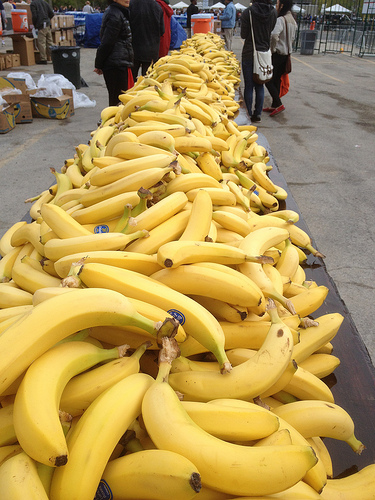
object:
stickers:
[94, 224, 110, 234]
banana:
[77, 263, 233, 373]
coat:
[94, 1, 138, 75]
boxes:
[49, 15, 80, 32]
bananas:
[157, 236, 265, 271]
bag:
[248, 10, 275, 80]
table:
[0, 37, 375, 499]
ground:
[1, 34, 373, 314]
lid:
[10, 8, 26, 12]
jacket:
[92, 2, 135, 74]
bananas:
[93, 446, 203, 500]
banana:
[36, 201, 95, 242]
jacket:
[238, 3, 277, 65]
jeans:
[240, 33, 264, 124]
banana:
[137, 129, 177, 154]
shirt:
[270, 12, 299, 58]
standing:
[236, 1, 273, 124]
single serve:
[74, 261, 236, 374]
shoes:
[268, 103, 285, 116]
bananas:
[290, 312, 344, 366]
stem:
[265, 300, 282, 323]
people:
[94, 0, 134, 111]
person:
[240, 0, 274, 124]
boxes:
[29, 91, 72, 120]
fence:
[297, 0, 374, 63]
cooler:
[188, 15, 213, 35]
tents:
[170, 2, 246, 14]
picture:
[0, 0, 375, 499]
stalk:
[174, 98, 181, 109]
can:
[48, 43, 84, 89]